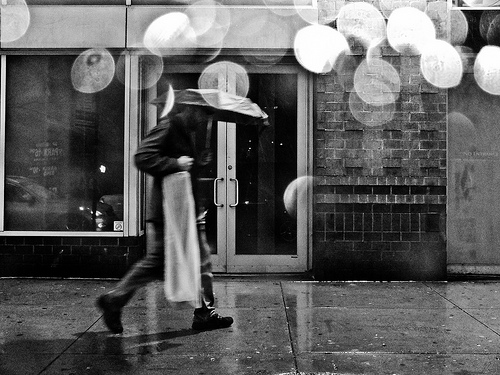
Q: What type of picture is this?
A: Black and white.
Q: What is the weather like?
A: Rainy.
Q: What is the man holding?
A: Umbrella.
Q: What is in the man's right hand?
A: Garment bag.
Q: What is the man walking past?
A: Doorway.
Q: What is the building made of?
A: Brick.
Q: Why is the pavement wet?
A: Rain.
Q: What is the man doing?
A: Walking.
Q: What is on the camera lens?
A: Rain.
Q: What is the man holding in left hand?
A: Umbrella.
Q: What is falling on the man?
A: Rain.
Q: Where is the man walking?
A: Sidewalk.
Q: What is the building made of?
A: Bricks.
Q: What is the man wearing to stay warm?
A: Coat.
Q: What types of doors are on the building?
A: Double doors.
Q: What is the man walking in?
A: The rain.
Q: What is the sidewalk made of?
A: Concrete.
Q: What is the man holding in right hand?
A: Dry cleaning.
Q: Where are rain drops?
A: Camera lens.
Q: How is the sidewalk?
A: Paved.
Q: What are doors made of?
A: Glass.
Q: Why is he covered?
A: Raining.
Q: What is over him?
A: Unbrellla.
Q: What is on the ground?
A: Water.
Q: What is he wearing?
A: Jacket.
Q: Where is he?
A: On the sidewalk.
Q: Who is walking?
A: The man.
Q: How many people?
A: 1.